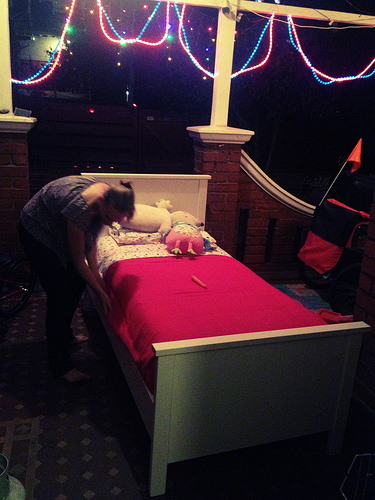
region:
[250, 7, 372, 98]
neon hanging lights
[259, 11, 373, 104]
pink and blue neon lights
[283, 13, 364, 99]
pink and blue hanging neon string lights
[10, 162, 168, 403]
Woman making childs bed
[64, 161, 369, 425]
White childs bed with pink comforter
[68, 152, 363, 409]
White childs bed with polka dot sheets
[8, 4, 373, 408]
Childs bed being made up outside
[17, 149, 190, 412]
Woman with hair in ponytail making bed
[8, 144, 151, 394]
Woman tucking in blanket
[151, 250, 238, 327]
Orange carrot ontop of pink blanket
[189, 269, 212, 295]
CARROT ON THE BED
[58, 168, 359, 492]
BED FRAME IS OF A WHITE COLOR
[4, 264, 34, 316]
BICYCLE IN THE ROOM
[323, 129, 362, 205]
ORANGE FLAG ON THE WHITE POLE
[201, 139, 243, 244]
A COLUMN MADE OF BRICK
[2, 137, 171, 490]
CARPETING IS ON THE FLOOR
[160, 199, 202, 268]
A STUFFED ANIMAL ON THE BED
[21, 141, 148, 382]
A WOMAN IS TUCKING IN THE BEDDING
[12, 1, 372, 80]
RED AND BLUE LIGHTS ARE OVERHEAD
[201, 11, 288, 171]
A TREE IS SEEN IN THE BACKGROUND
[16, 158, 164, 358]
woman is making up bed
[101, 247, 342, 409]
bed cover is red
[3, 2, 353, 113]
lights hanging above bed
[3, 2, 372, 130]
white post above bed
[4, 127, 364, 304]
structure made of brick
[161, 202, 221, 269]
stuffed animal laying on bed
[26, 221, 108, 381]
woman's pants are black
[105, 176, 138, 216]
woman's hair in pony tail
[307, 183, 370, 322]
wheel chair near bed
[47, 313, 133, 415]
woman not wearing shoes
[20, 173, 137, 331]
woman in a blue shirt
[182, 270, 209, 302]
carrot on the bed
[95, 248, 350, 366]
red bed spread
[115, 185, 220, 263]
stuffed animals on the pillow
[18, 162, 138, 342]
woman making a bed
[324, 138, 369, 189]
an orange flag on a white pole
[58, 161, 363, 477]
a twin sized bed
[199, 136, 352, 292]
the sloped brick wall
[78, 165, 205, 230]
the white headboard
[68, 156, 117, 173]
lights in the distance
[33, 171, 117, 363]
Woman making a bed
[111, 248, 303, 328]
Pink blanket on a bed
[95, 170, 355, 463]
Bed with white headboard and footboard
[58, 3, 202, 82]
Lights hanging from the ceiling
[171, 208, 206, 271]
Stuffed doll on a bed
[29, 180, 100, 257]
Woman wearing a plaid shirt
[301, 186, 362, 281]
Red and Black blanket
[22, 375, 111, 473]
Gray plaid carpet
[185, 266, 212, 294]
Toy on a bed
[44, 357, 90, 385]
Woman without shoes